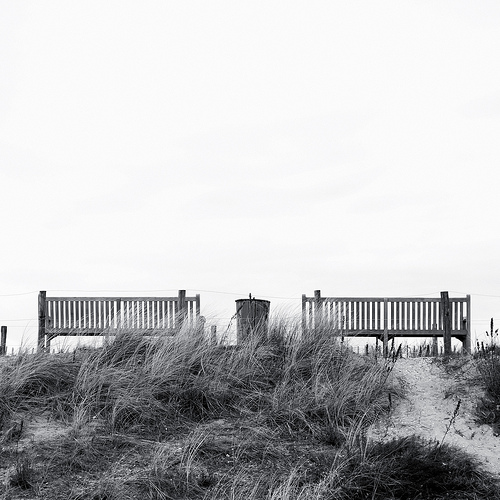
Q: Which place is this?
A: It is a beach.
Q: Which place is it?
A: It is a beach.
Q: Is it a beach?
A: Yes, it is a beach.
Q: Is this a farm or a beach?
A: It is a beach.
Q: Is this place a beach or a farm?
A: It is a beach.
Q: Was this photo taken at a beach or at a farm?
A: It was taken at a beach.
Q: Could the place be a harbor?
A: No, it is a beach.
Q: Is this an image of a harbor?
A: No, the picture is showing a beach.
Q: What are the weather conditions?
A: It is clear.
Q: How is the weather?
A: It is clear.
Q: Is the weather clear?
A: Yes, it is clear.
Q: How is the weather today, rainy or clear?
A: It is clear.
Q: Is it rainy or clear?
A: It is clear.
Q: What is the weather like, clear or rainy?
A: It is clear.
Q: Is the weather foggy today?
A: No, it is clear.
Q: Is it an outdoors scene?
A: Yes, it is outdoors.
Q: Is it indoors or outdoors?
A: It is outdoors.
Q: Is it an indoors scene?
A: No, it is outdoors.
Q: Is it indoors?
A: No, it is outdoors.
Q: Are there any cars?
A: No, there are no cars.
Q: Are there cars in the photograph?
A: No, there are no cars.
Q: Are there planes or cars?
A: No, there are no cars or planes.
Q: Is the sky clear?
A: Yes, the sky is clear.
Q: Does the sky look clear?
A: Yes, the sky is clear.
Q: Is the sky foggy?
A: No, the sky is clear.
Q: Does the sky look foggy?
A: No, the sky is clear.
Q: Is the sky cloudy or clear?
A: The sky is clear.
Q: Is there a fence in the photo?
A: Yes, there is a fence.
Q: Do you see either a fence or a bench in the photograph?
A: Yes, there is a fence.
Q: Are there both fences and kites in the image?
A: No, there is a fence but no kites.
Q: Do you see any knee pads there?
A: No, there are no knee pads.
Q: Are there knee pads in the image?
A: No, there are no knee pads.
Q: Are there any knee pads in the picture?
A: No, there are no knee pads.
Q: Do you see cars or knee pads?
A: No, there are no knee pads or cars.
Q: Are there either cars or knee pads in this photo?
A: No, there are no knee pads or cars.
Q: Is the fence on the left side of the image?
A: Yes, the fence is on the left of the image.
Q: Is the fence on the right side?
A: No, the fence is on the left of the image.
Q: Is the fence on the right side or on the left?
A: The fence is on the left of the image.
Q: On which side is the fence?
A: The fence is on the left of the image.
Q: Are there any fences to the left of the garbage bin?
A: Yes, there is a fence to the left of the garbage bin.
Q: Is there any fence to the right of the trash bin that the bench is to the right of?
A: No, the fence is to the left of the garbage can.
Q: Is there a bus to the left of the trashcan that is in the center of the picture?
A: No, there is a fence to the left of the garbage bin.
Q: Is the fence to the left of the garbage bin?
A: Yes, the fence is to the left of the garbage bin.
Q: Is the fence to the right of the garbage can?
A: No, the fence is to the left of the garbage can.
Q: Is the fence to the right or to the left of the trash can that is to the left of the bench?
A: The fence is to the left of the garbage can.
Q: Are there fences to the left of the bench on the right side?
A: Yes, there is a fence to the left of the bench.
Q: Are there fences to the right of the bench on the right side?
A: No, the fence is to the left of the bench.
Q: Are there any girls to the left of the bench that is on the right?
A: No, there is a fence to the left of the bench.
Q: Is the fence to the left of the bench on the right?
A: Yes, the fence is to the left of the bench.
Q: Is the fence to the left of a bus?
A: No, the fence is to the left of the bench.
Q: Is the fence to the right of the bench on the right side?
A: No, the fence is to the left of the bench.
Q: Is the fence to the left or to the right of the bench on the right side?
A: The fence is to the left of the bench.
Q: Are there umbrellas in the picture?
A: No, there are no umbrellas.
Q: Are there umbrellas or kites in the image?
A: No, there are no umbrellas or kites.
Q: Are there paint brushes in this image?
A: No, there are no paint brushes.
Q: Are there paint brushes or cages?
A: No, there are no paint brushes or cages.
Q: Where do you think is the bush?
A: The bush is on the beach.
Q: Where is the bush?
A: The bush is on the beach.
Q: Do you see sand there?
A: Yes, there is sand.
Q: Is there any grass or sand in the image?
A: Yes, there is sand.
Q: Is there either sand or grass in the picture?
A: Yes, there is sand.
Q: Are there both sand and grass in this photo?
A: Yes, there are both sand and grass.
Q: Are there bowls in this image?
A: No, there are no bowls.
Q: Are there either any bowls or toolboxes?
A: No, there are no bowls or toolboxes.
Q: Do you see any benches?
A: Yes, there is a bench.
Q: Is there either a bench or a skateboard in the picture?
A: Yes, there is a bench.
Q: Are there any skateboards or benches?
A: Yes, there is a bench.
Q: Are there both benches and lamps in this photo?
A: No, there is a bench but no lamps.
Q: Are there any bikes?
A: No, there are no bikes.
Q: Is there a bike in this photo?
A: No, there are no bikes.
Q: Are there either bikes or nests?
A: No, there are no bikes or nests.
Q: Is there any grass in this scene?
A: Yes, there is grass.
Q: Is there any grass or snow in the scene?
A: Yes, there is grass.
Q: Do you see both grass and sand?
A: Yes, there are both grass and sand.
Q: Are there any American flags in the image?
A: No, there are no American flags.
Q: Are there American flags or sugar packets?
A: No, there are no American flags or sugar packets.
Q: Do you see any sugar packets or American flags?
A: No, there are no American flags or sugar packets.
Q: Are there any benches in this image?
A: Yes, there is a bench.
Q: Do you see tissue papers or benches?
A: Yes, there is a bench.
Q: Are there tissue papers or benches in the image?
A: Yes, there is a bench.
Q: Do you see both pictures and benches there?
A: No, there is a bench but no pictures.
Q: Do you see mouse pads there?
A: No, there are no mouse pads.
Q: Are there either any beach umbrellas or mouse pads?
A: No, there are no mouse pads or beach umbrellas.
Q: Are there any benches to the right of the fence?
A: Yes, there is a bench to the right of the fence.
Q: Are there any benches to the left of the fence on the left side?
A: No, the bench is to the right of the fence.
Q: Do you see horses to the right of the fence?
A: No, there is a bench to the right of the fence.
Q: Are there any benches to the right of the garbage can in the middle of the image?
A: Yes, there is a bench to the right of the trash can.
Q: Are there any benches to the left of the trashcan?
A: No, the bench is to the right of the trashcan.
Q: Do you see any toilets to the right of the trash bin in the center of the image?
A: No, there is a bench to the right of the garbage can.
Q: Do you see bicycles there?
A: No, there are no bicycles.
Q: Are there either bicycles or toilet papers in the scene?
A: No, there are no bicycles or toilet papers.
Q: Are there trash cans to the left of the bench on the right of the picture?
A: Yes, there is a trash can to the left of the bench.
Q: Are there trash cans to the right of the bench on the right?
A: No, the trash can is to the left of the bench.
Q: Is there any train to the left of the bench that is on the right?
A: No, there is a trash can to the left of the bench.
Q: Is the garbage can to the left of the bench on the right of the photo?
A: Yes, the garbage can is to the left of the bench.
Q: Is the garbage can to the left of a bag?
A: No, the garbage can is to the left of the bench.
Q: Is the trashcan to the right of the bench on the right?
A: No, the trashcan is to the left of the bench.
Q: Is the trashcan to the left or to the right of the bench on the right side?
A: The trashcan is to the left of the bench.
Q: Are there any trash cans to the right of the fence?
A: Yes, there is a trash can to the right of the fence.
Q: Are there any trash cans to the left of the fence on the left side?
A: No, the trash can is to the right of the fence.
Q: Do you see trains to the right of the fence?
A: No, there is a trash can to the right of the fence.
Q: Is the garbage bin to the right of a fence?
A: Yes, the garbage bin is to the right of a fence.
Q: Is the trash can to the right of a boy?
A: No, the trash can is to the right of a fence.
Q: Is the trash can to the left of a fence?
A: No, the trash can is to the right of a fence.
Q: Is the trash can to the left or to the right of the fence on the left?
A: The trash can is to the right of the fence.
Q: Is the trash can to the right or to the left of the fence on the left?
A: The trash can is to the right of the fence.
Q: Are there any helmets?
A: No, there are no helmets.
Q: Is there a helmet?
A: No, there are no helmets.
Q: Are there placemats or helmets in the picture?
A: No, there are no helmets or placemats.